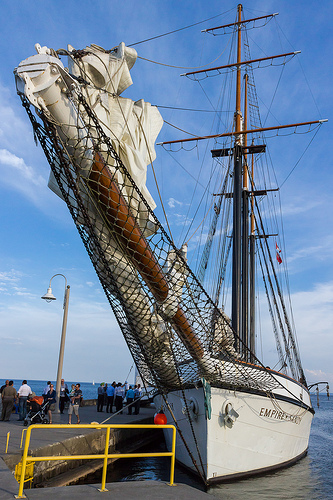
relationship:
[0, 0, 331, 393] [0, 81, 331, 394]
sky has clouds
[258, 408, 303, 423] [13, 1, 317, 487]
lettering on boat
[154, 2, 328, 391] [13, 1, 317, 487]
sail on boat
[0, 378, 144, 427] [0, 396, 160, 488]
people walking on pier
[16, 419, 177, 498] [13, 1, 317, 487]
rail near boat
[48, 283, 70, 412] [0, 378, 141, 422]
post near people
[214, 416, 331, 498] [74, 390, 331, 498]
ripples on water